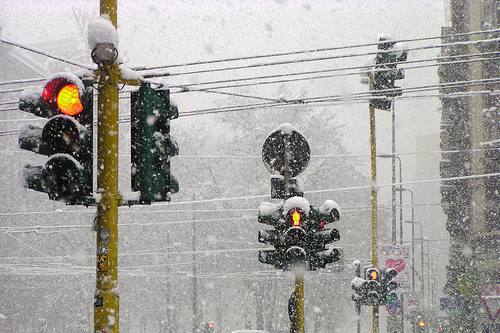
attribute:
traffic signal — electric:
[363, 31, 408, 116]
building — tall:
[428, 5, 498, 313]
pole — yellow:
[91, 1, 121, 331]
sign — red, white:
[368, 237, 424, 303]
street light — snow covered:
[359, 35, 408, 112]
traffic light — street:
[18, 64, 181, 205]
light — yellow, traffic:
[55, 85, 83, 114]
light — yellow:
[287, 207, 303, 228]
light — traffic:
[12, 65, 114, 206]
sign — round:
[246, 108, 328, 196]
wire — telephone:
[152, 17, 494, 136]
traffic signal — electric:
[268, 160, 373, 297]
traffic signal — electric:
[126, 75, 180, 205]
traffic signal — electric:
[16, 62, 97, 214]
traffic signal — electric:
[252, 170, 344, 276]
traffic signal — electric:
[345, 257, 399, 310]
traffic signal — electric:
[365, 268, 377, 305]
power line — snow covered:
[2, 26, 499, 301]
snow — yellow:
[85, 12, 120, 47]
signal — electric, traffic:
[14, 72, 91, 197]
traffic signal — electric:
[255, 196, 285, 272]